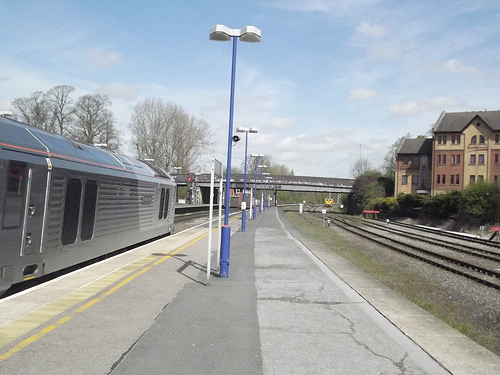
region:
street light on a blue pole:
[238, 25, 261, 43]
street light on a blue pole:
[206, 22, 233, 42]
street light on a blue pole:
[247, 126, 259, 133]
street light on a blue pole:
[235, 123, 247, 133]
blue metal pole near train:
[212, 36, 239, 280]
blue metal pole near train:
[237, 130, 249, 232]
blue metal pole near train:
[248, 156, 259, 223]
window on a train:
[57, 175, 87, 250]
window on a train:
[77, 175, 102, 246]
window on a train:
[152, 185, 166, 225]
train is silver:
[106, 164, 147, 243]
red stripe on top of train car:
[38, 135, 67, 162]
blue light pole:
[222, 55, 232, 273]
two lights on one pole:
[210, 21, 274, 44]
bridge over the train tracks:
[198, 156, 363, 209]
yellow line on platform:
[104, 282, 126, 306]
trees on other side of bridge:
[144, 106, 214, 179]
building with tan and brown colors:
[451, 144, 477, 179]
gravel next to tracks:
[401, 251, 431, 285]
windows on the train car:
[60, 161, 104, 254]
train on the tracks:
[1, 112, 204, 302]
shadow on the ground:
[149, 241, 210, 293]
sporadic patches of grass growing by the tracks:
[293, 206, 493, 349]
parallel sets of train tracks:
[346, 206, 499, 299]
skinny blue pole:
[214, 42, 246, 286]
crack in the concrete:
[330, 306, 368, 350]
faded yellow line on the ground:
[4, 263, 161, 370]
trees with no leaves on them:
[11, 78, 208, 178]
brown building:
[352, 107, 499, 207]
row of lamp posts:
[203, 14, 287, 289]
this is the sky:
[142, 11, 169, 57]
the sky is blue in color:
[150, 20, 185, 67]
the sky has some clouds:
[359, 8, 427, 96]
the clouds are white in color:
[353, 30, 414, 90]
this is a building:
[389, 110, 493, 203]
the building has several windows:
[430, 135, 498, 191]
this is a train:
[0, 118, 182, 289]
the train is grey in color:
[96, 165, 146, 213]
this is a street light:
[211, 16, 261, 64]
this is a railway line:
[184, 205, 194, 218]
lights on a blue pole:
[188, 21, 270, 284]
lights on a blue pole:
[234, 124, 263, 237]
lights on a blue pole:
[246, 151, 266, 226]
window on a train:
[162, 186, 171, 222]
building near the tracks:
[430, 100, 498, 203]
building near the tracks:
[396, 129, 434, 204]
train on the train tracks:
[0, 113, 189, 301]